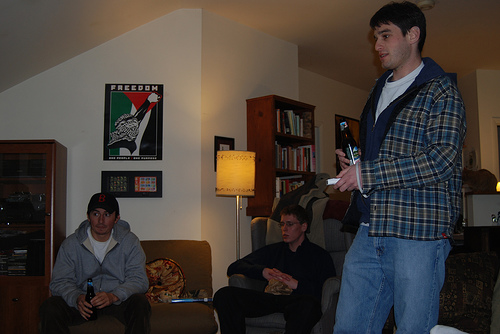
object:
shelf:
[274, 167, 320, 179]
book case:
[246, 91, 330, 220]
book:
[307, 142, 319, 172]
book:
[289, 111, 298, 135]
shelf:
[274, 132, 314, 146]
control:
[326, 177, 348, 189]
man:
[329, 0, 468, 333]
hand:
[334, 163, 359, 193]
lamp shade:
[214, 148, 256, 196]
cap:
[85, 192, 124, 215]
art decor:
[102, 82, 160, 162]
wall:
[0, 7, 202, 241]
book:
[287, 145, 298, 170]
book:
[274, 107, 283, 135]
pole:
[231, 192, 244, 262]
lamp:
[212, 149, 259, 270]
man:
[38, 190, 152, 333]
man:
[210, 202, 336, 333]